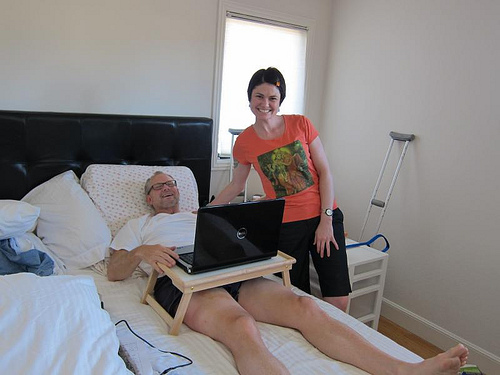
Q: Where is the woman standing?
A: Beside bed.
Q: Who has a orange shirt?
A: The woman.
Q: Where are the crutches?
A: Against the wall.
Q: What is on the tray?
A: Black laptop.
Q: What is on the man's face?
A: Eyeglasses.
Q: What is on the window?
A: Roll down shade.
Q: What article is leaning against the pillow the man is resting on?
A: Another pillow.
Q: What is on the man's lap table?
A: A laptop computer.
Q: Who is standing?
A: A woman.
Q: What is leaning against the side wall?
A: Crutch.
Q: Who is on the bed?
A: Man.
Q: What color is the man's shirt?
A: White.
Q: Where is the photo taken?
A: Bedroom.